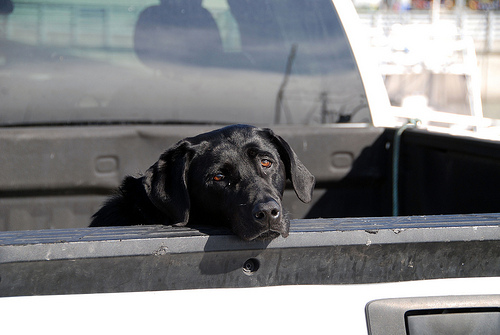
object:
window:
[0, 0, 373, 126]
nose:
[252, 201, 281, 224]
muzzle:
[240, 201, 290, 242]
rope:
[392, 123, 413, 216]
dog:
[88, 124, 316, 242]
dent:
[137, 131, 144, 139]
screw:
[246, 263, 252, 269]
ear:
[142, 146, 197, 226]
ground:
[330, 145, 377, 200]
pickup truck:
[0, 0, 499, 335]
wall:
[183, 18, 287, 118]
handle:
[363, 295, 499, 335]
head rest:
[134, 0, 223, 66]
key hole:
[243, 258, 261, 276]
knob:
[333, 154, 352, 167]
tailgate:
[0, 213, 499, 335]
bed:
[0, 126, 500, 334]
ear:
[264, 128, 316, 204]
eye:
[261, 159, 272, 167]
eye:
[214, 174, 225, 180]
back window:
[0, 0, 372, 125]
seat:
[134, 0, 257, 103]